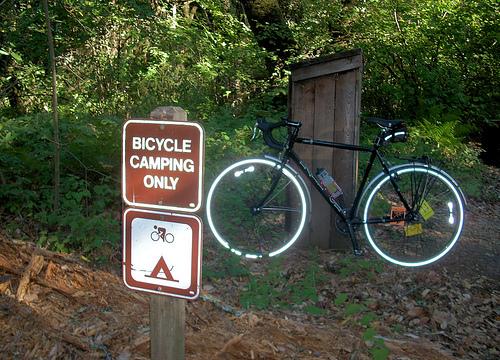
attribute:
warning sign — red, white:
[121, 207, 201, 299]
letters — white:
[128, 131, 200, 206]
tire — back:
[428, 259, 445, 266]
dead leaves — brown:
[350, 272, 498, 345]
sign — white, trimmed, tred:
[131, 199, 211, 293]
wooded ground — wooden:
[0, 233, 455, 358]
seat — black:
[353, 112, 443, 147]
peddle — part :
[344, 237, 384, 264]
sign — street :
[118, 116, 206, 306]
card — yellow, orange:
[405, 222, 422, 236]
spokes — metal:
[210, 162, 301, 254]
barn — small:
[277, 41, 370, 258]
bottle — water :
[312, 161, 347, 208]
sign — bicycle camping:
[93, 125, 217, 284]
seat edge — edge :
[364, 110, 409, 137]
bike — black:
[205, 123, 467, 269]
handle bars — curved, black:
[250, 110, 290, 145]